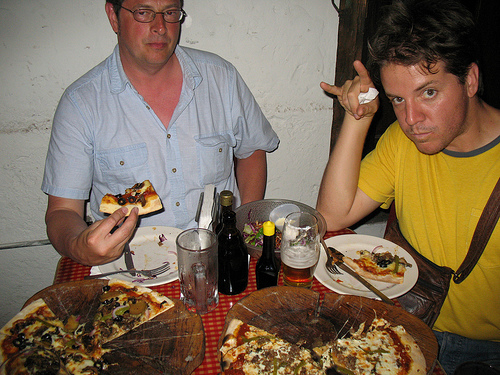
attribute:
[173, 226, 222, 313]
glass — clear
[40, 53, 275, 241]
shirt — blue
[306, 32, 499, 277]
man — leather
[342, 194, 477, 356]
bag — brown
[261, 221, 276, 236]
cap — yellow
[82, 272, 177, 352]
pizza — sliced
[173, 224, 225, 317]
glass — dirty, empty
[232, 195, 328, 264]
bowl — Metal 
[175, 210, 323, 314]
glasses — beer 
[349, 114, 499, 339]
shirt — yellow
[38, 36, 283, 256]
shirt — light blue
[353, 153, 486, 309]
shirt — yellow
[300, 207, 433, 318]
plate — white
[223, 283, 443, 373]
pizza tray — black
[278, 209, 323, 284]
glass — mostly empty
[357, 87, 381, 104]
napkin — white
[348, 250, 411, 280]
pizza — half eaten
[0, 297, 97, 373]
pizza — Vegetable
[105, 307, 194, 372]
cutting board — wooden 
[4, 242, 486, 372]
table cloth — red